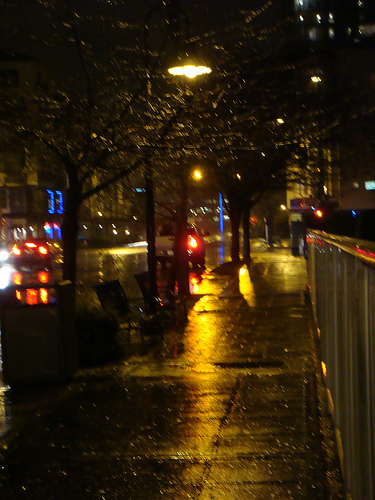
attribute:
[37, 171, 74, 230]
lights — blue 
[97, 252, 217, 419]
benches — black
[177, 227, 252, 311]
lights — red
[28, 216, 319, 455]
road — rainy , wet 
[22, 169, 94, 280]
lights — blue 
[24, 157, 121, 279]
lights — blue , red 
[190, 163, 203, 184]
light — yellow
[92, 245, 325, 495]
sidewalk — dark, wet, shiny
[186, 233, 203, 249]
tail light — red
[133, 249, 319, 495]
sidewalk — long, wet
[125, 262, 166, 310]
can — dark, large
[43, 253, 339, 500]
sidewalk — wet, reflecting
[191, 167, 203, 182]
light — reflecting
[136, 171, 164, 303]
poles — metal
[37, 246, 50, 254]
lights — activated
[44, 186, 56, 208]
sign — blue, neon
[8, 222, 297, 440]
street — wet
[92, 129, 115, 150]
branches — wet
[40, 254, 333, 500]
concrete — black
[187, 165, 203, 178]
light — overhead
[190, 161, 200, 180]
light — yellow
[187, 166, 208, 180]
light — bright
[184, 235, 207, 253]
lights — red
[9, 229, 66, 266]
truck — moving